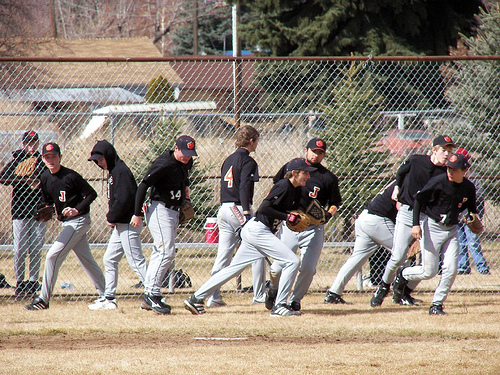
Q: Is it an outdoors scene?
A: Yes, it is outdoors.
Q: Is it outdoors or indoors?
A: It is outdoors.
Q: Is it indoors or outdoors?
A: It is outdoors.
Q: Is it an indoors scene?
A: No, it is outdoors.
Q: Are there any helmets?
A: No, there are no helmets.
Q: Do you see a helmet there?
A: No, there are no helmets.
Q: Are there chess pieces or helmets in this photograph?
A: No, there are no helmets or chess pieces.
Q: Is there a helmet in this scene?
A: No, there are no helmets.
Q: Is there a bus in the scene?
A: No, there are no buses.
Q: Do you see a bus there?
A: No, there are no buses.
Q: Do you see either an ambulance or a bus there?
A: No, there are no buses or ambulances.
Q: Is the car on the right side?
A: Yes, the car is on the right of the image.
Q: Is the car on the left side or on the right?
A: The car is on the right of the image.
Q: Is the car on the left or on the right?
A: The car is on the right of the image.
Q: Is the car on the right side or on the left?
A: The car is on the right of the image.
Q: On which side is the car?
A: The car is on the right of the image.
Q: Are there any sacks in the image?
A: No, there are no sacks.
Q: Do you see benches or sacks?
A: No, there are no sacks or benches.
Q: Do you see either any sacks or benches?
A: No, there are no sacks or benches.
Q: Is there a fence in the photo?
A: Yes, there is a fence.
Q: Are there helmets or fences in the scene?
A: Yes, there is a fence.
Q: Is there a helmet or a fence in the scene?
A: Yes, there is a fence.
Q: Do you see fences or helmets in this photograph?
A: Yes, there is a fence.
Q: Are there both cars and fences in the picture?
A: Yes, there are both a fence and a car.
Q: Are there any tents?
A: No, there are no tents.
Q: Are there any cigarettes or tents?
A: No, there are no tents or cigarettes.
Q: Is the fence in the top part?
A: Yes, the fence is in the top of the image.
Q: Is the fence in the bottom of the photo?
A: No, the fence is in the top of the image.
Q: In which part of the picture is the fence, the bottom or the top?
A: The fence is in the top of the image.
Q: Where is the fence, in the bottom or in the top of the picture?
A: The fence is in the top of the image.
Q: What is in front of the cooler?
A: The fence is in front of the cooler.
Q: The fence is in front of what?
A: The fence is in front of the cooler.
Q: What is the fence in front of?
A: The fence is in front of the cooler.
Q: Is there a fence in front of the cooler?
A: Yes, there is a fence in front of the cooler.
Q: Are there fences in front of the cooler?
A: Yes, there is a fence in front of the cooler.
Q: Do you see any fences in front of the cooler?
A: Yes, there is a fence in front of the cooler.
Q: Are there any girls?
A: No, there are no girls.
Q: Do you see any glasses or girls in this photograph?
A: No, there are no girls or glasses.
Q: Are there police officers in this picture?
A: No, there are no police officers.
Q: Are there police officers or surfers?
A: No, there are no police officers or surfers.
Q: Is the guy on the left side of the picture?
A: Yes, the guy is on the left of the image.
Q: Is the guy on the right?
A: No, the guy is on the left of the image.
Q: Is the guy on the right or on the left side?
A: The guy is on the left of the image.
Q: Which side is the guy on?
A: The guy is on the left of the image.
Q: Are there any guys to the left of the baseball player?
A: Yes, there is a guy to the left of the player.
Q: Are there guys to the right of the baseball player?
A: No, the guy is to the left of the player.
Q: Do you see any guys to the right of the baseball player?
A: No, the guy is to the left of the player.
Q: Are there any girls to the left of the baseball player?
A: No, there is a guy to the left of the player.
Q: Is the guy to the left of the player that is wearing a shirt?
A: Yes, the guy is to the left of the player.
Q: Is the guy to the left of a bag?
A: No, the guy is to the left of the player.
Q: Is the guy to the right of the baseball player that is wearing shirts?
A: No, the guy is to the left of the player.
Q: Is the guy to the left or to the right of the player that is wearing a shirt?
A: The guy is to the left of the player.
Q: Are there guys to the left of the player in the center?
A: Yes, there is a guy to the left of the player.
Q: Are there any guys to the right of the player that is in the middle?
A: No, the guy is to the left of the player.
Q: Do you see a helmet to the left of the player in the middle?
A: No, there is a guy to the left of the player.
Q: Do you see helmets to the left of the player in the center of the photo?
A: No, there is a guy to the left of the player.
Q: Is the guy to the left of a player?
A: Yes, the guy is to the left of a player.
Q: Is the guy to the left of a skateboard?
A: No, the guy is to the left of a player.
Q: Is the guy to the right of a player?
A: No, the guy is to the left of a player.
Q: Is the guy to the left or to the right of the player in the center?
A: The guy is to the left of the player.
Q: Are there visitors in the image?
A: No, there are no visitors.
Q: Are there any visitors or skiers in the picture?
A: No, there are no visitors or skiers.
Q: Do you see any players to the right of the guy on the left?
A: Yes, there is a player to the right of the guy.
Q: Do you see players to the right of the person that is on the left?
A: Yes, there is a player to the right of the guy.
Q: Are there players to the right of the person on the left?
A: Yes, there is a player to the right of the guy.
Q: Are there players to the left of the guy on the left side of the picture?
A: No, the player is to the right of the guy.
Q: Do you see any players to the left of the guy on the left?
A: No, the player is to the right of the guy.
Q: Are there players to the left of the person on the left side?
A: No, the player is to the right of the guy.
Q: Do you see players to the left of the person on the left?
A: No, the player is to the right of the guy.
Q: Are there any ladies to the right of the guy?
A: No, there is a player to the right of the guy.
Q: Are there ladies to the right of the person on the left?
A: No, there is a player to the right of the guy.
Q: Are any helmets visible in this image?
A: No, there are no helmets.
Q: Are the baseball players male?
A: Yes, the baseball players are male.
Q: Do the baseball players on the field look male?
A: Yes, the baseball players are male.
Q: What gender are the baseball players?
A: The baseball players are male.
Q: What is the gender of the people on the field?
A: The baseball players are male.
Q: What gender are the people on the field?
A: The baseball players are male.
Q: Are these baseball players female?
A: No, the baseball players are male.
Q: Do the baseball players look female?
A: No, the baseball players are male.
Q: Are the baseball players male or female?
A: The baseball players are male.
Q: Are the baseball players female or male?
A: The baseball players are male.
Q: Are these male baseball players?
A: Yes, these are male baseball players.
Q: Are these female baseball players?
A: No, these are male baseball players.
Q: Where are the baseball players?
A: The baseball players are on the field.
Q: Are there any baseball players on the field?
A: Yes, there are baseball players on the field.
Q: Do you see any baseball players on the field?
A: Yes, there are baseball players on the field.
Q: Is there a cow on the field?
A: No, there are baseball players on the field.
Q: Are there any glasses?
A: No, there are no glasses.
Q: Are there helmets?
A: No, there are no helmets.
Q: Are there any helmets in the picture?
A: No, there are no helmets.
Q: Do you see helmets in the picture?
A: No, there are no helmets.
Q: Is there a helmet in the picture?
A: No, there are no helmets.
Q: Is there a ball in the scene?
A: No, there are no balls.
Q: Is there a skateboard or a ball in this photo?
A: No, there are no balls or skateboards.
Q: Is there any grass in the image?
A: Yes, there is grass.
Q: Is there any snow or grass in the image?
A: Yes, there is grass.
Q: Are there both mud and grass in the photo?
A: No, there is grass but no mud.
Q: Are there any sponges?
A: No, there are no sponges.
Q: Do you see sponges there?
A: No, there are no sponges.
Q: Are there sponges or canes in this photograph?
A: No, there are no sponges or canes.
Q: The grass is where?
A: The grass is on the field.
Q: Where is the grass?
A: The grass is on the field.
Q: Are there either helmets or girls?
A: No, there are no girls or helmets.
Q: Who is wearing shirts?
A: The player is wearing shirts.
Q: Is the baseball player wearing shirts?
A: Yes, the player is wearing shirts.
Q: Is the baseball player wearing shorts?
A: No, the player is wearing shirts.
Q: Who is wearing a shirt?
A: The player is wearing a shirt.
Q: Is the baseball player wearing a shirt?
A: Yes, the player is wearing a shirt.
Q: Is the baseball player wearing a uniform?
A: No, the player is wearing a shirt.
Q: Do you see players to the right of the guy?
A: Yes, there is a player to the right of the guy.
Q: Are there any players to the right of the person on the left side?
A: Yes, there is a player to the right of the guy.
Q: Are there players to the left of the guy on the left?
A: No, the player is to the right of the guy.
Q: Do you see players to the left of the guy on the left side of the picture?
A: No, the player is to the right of the guy.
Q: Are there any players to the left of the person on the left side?
A: No, the player is to the right of the guy.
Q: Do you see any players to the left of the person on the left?
A: No, the player is to the right of the guy.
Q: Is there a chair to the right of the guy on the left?
A: No, there is a player to the right of the guy.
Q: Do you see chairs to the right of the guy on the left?
A: No, there is a player to the right of the guy.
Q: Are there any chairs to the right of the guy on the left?
A: No, there is a player to the right of the guy.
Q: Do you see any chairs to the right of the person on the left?
A: No, there is a player to the right of the guy.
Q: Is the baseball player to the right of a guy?
A: Yes, the player is to the right of a guy.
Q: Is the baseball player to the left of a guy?
A: No, the player is to the right of a guy.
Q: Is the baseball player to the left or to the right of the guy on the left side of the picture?
A: The player is to the right of the guy.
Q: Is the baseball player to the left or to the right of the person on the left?
A: The player is to the right of the guy.